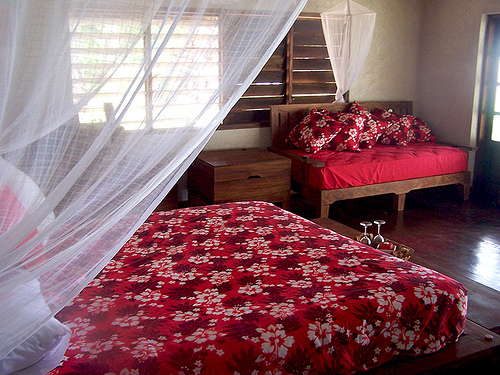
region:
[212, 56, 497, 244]
a ouch with pillows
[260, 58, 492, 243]
a couch with red cushions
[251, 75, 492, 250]
a couch that is wood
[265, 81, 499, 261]
a brown wooden couch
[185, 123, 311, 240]
a brown wood table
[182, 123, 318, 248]
a table that is wood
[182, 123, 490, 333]
a table that is brown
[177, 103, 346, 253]
a table that is brown wood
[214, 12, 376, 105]
windows with wooden blinds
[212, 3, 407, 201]
window with brown wooden blinds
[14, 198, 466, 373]
matress with a red and white sheet on it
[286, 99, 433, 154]
red pillows with white flowers on them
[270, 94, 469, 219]
wooden bench in the room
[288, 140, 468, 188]
matress on top of the wooden bench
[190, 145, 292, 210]
wooden dresser next to the couch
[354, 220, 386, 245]
two wine glasses at the foot of the bed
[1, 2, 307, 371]
white drapes over the bed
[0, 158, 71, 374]
red and white pillows on the bed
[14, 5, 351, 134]
windows in the room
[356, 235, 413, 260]
basket with wine glasses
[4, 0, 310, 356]
shear sheet above the bed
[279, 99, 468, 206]
sofa in the corner of the room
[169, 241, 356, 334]
flowers on the bedspread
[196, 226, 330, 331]
flowers are red and white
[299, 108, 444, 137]
pillows on the sofa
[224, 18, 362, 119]
wooden blinds on the window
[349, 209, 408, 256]
glasses at the end of the bed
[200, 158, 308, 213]
dresser next to sofa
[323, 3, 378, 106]
white shear cover hanging over sofa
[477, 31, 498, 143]
light coming in from door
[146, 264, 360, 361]
a bed spread with a floral print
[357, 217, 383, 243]
two wine glasses in a basket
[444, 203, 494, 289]
hard wood flooring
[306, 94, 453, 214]
a wood bed frame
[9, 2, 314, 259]
a white net over a bed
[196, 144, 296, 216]
a wood chest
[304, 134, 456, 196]
a red bed sheet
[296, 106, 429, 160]
pillows with a floral print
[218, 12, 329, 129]
a wood window blind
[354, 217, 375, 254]
a wine glass in a basket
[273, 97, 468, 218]
There are pillows on the couch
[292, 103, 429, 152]
The pillow are red and white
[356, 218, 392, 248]
Two wine glasses are upside down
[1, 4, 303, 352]
The curtain is white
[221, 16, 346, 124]
The window blinds are brown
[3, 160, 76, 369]
The pillows are red and white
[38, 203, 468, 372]
The bed spread has a flower pattern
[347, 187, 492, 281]
The flooring is dark wood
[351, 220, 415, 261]
The wine glasses are on a wood tray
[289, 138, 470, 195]
The couch cushion is red